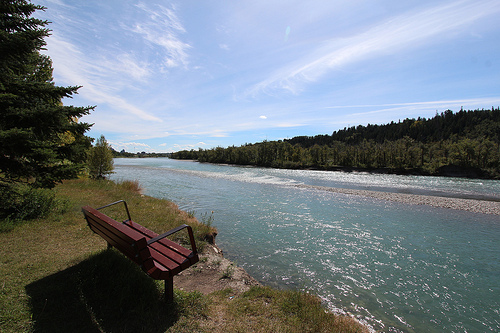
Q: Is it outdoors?
A: Yes, it is outdoors.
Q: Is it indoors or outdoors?
A: It is outdoors.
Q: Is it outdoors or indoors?
A: It is outdoors.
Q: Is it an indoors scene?
A: No, it is outdoors.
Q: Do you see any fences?
A: No, there are no fences.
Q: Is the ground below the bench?
A: Yes, the ground is below the bench.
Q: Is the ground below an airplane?
A: No, the ground is below the bench.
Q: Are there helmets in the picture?
A: No, there are no helmets.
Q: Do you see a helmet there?
A: No, there are no helmets.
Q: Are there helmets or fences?
A: No, there are no helmets or fences.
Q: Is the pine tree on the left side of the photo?
A: Yes, the pine tree is on the left of the image.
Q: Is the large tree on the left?
A: Yes, the pine tree is on the left of the image.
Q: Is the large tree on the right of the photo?
A: No, the pine tree is on the left of the image.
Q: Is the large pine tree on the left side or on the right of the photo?
A: The pine is on the left of the image.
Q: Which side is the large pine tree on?
A: The pine tree is on the left of the image.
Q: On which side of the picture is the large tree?
A: The pine tree is on the left of the image.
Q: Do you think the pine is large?
A: Yes, the pine is large.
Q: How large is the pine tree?
A: The pine tree is large.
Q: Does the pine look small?
A: No, the pine is large.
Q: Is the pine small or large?
A: The pine is large.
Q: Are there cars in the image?
A: No, there are no cars.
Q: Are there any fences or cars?
A: No, there are no cars or fences.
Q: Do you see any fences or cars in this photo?
A: No, there are no cars or fences.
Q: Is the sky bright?
A: Yes, the sky is bright.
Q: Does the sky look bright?
A: Yes, the sky is bright.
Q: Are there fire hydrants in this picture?
A: No, there are no fire hydrants.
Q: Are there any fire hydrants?
A: No, there are no fire hydrants.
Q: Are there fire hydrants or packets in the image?
A: No, there are no fire hydrants or packets.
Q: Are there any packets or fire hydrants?
A: No, there are no fire hydrants or packets.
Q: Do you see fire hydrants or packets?
A: No, there are no fire hydrants or packets.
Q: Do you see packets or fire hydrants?
A: No, there are no fire hydrants or packets.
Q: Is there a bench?
A: Yes, there is a bench.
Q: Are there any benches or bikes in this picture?
A: Yes, there is a bench.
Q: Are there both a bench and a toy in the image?
A: No, there is a bench but no toys.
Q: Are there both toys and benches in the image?
A: No, there is a bench but no toys.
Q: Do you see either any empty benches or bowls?
A: Yes, there is an empty bench.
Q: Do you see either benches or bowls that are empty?
A: Yes, the bench is empty.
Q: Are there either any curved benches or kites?
A: Yes, there is a curved bench.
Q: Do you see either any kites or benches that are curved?
A: Yes, the bench is curved.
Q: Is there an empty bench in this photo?
A: Yes, there is an empty bench.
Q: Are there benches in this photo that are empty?
A: Yes, there is a bench that is empty.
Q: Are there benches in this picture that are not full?
A: Yes, there is a empty bench.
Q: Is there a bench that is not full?
A: Yes, there is a empty bench.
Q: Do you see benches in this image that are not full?
A: Yes, there is a empty bench.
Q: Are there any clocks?
A: No, there are no clocks.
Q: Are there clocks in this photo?
A: No, there are no clocks.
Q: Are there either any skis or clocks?
A: No, there are no clocks or skis.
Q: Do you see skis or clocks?
A: No, there are no clocks or skis.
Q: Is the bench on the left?
A: Yes, the bench is on the left of the image.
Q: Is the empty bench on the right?
A: No, the bench is on the left of the image.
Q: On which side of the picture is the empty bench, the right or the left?
A: The bench is on the left of the image.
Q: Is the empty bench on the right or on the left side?
A: The bench is on the left of the image.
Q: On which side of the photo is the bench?
A: The bench is on the left of the image.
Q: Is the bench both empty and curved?
A: Yes, the bench is empty and curved.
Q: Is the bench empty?
A: Yes, the bench is empty.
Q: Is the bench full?
A: No, the bench is empty.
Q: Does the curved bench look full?
A: No, the bench is empty.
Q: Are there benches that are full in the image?
A: No, there is a bench but it is empty.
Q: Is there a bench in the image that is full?
A: No, there is a bench but it is empty.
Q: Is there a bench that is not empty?
A: No, there is a bench but it is empty.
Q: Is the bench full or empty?
A: The bench is empty.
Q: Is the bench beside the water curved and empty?
A: Yes, the bench is curved and empty.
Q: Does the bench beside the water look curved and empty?
A: Yes, the bench is curved and empty.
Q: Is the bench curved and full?
A: No, the bench is curved but empty.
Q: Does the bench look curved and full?
A: No, the bench is curved but empty.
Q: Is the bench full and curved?
A: No, the bench is curved but empty.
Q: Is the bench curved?
A: Yes, the bench is curved.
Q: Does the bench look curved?
A: Yes, the bench is curved.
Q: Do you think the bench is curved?
A: Yes, the bench is curved.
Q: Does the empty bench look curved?
A: Yes, the bench is curved.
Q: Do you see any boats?
A: No, there are no boats.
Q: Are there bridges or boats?
A: No, there are no boats or bridges.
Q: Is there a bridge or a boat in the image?
A: No, there are no boats or bridges.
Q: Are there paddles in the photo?
A: No, there are no paddles.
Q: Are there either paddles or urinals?
A: No, there are no paddles or urinals.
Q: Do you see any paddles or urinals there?
A: No, there are no paddles or urinals.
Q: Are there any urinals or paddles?
A: No, there are no paddles or urinals.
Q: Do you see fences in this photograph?
A: No, there are no fences.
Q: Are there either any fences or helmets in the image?
A: No, there are no fences or helmets.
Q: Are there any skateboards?
A: No, there are no skateboards.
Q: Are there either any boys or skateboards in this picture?
A: No, there are no skateboards or boys.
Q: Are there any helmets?
A: No, there are no helmets.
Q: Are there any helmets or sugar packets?
A: No, there are no helmets or sugar packets.